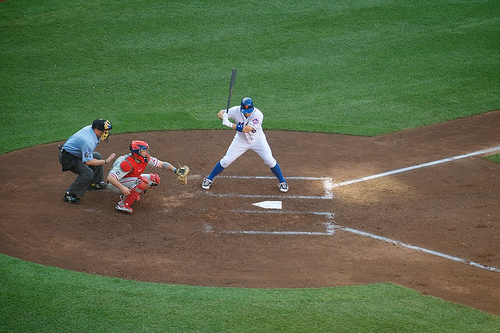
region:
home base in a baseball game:
[239, 193, 300, 218]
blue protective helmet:
[236, 93, 256, 115]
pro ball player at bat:
[199, 61, 298, 202]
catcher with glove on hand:
[108, 139, 198, 216]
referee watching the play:
[51, 107, 121, 211]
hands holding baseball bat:
[215, 61, 242, 131]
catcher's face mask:
[127, 138, 148, 161]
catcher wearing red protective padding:
[107, 139, 193, 215]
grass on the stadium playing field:
[71, 11, 363, 88]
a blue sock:
[262, 161, 289, 186]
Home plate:
[252, 190, 317, 246]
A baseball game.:
[47, 60, 384, 245]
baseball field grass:
[312, 50, 407, 116]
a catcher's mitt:
[175, 151, 193, 187]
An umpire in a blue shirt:
[60, 121, 102, 171]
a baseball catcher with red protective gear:
[96, 145, 166, 207]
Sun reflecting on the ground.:
[340, 150, 425, 230]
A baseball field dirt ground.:
[180, 240, 311, 280]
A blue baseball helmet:
[240, 100, 265, 120]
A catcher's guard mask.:
[135, 145, 150, 156]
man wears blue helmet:
[233, 87, 263, 119]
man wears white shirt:
[213, 64, 265, 154]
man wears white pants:
[213, 122, 284, 184]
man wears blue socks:
[214, 149, 296, 171]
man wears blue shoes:
[196, 169, 297, 221]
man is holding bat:
[201, 68, 251, 123]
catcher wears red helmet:
[119, 121, 166, 168]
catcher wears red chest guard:
[113, 152, 150, 197]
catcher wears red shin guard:
[123, 181, 152, 213]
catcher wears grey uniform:
[107, 172, 139, 216]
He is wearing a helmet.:
[225, 90, 283, 125]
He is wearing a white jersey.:
[210, 97, 296, 190]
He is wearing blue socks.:
[190, 144, 346, 222]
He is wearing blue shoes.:
[188, 165, 325, 213]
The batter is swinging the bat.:
[196, 60, 300, 145]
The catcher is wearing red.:
[90, 122, 220, 234]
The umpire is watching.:
[43, 109, 129, 190]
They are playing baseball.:
[25, 26, 387, 256]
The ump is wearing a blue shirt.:
[46, 101, 124, 208]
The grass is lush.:
[53, 24, 228, 129]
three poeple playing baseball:
[37, 2, 312, 269]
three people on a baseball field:
[40, 13, 344, 259]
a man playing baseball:
[183, 42, 340, 239]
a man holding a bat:
[187, 45, 342, 247]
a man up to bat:
[194, 49, 313, 243]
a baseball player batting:
[191, 42, 329, 213]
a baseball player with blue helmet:
[189, 63, 307, 221]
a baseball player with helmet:
[150, 42, 345, 242]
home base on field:
[229, 172, 307, 249]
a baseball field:
[37, 22, 391, 332]